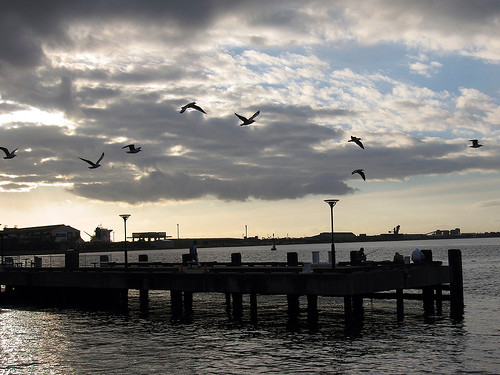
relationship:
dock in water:
[1, 247, 465, 332] [1, 235, 498, 375]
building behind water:
[0, 222, 82, 251] [1, 235, 498, 375]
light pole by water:
[175, 222, 181, 240] [1, 235, 498, 375]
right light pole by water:
[244, 223, 249, 242] [1, 235, 498, 375]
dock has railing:
[1, 247, 465, 332] [0, 251, 114, 271]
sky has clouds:
[1, 1, 500, 244] [1, 1, 500, 206]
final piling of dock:
[446, 246, 466, 311] [1, 247, 465, 332]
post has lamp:
[123, 217, 129, 272] [118, 212, 131, 221]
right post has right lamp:
[329, 205, 337, 270] [323, 199, 340, 208]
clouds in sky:
[1, 1, 500, 206] [1, 1, 500, 244]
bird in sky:
[233, 108, 262, 129] [1, 1, 500, 244]